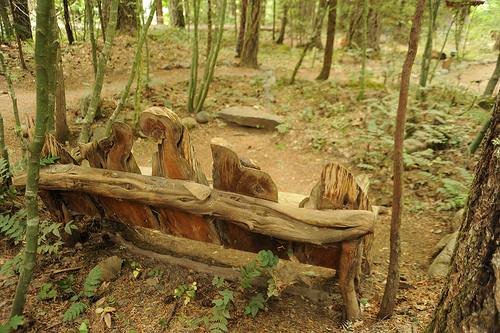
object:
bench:
[11, 105, 380, 321]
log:
[13, 162, 376, 246]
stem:
[103, 0, 163, 137]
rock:
[216, 106, 284, 129]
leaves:
[61, 301, 88, 321]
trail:
[0, 62, 499, 147]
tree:
[103, 0, 141, 36]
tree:
[9, 0, 34, 42]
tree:
[166, 0, 186, 28]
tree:
[345, 0, 382, 63]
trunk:
[377, 0, 426, 321]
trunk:
[3, 0, 57, 332]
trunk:
[424, 105, 500, 332]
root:
[189, 109, 203, 113]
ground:
[1, 23, 500, 331]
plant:
[208, 249, 277, 331]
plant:
[55, 263, 105, 322]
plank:
[284, 163, 373, 309]